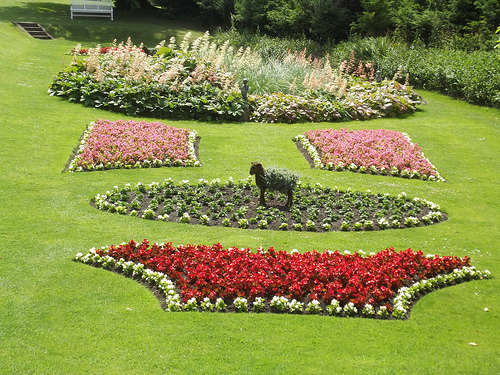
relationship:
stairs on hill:
[11, 14, 59, 44] [3, 10, 211, 60]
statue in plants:
[239, 76, 252, 111] [100, 23, 432, 114]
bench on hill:
[63, 1, 119, 25] [3, 1, 200, 55]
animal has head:
[246, 160, 302, 212] [247, 160, 267, 179]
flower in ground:
[105, 243, 465, 314] [6, 3, 498, 373]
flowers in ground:
[184, 263, 213, 285] [166, 231, 419, 243]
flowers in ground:
[116, 110, 491, 320] [6, 3, 498, 373]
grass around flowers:
[43, 89, 410, 354] [116, 110, 491, 320]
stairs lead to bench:
[11, 14, 59, 44] [67, 2, 114, 21]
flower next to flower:
[303, 283, 316, 296] [371, 280, 387, 295]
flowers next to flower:
[116, 110, 491, 320] [92, 248, 107, 257]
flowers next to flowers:
[116, 110, 491, 320] [116, 110, 491, 320]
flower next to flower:
[291, 297, 301, 315] [303, 296, 323, 315]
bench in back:
[63, 1, 119, 25] [104, 151, 433, 352]